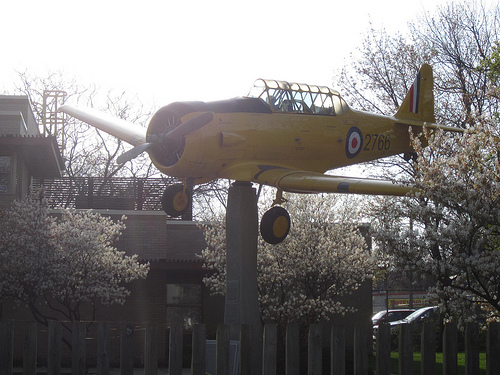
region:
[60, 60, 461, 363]
yellow plane on top of pillar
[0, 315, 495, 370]
wooden fence with grey pickets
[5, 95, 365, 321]
house with different levels and angles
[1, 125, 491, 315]
blossoms on round trees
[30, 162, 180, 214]
railing on elevated floor of house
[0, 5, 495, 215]
bright light over trees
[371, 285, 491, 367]
cars and truck parked by green lawn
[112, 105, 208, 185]
silver propeller in front of circular opening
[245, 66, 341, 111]
curved metal frame over cockpit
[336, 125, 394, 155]
circle with rings next to numbers on side of plane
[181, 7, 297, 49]
White clear cloudless sky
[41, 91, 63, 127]
Big steady metal frame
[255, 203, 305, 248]
Black and yellow wheel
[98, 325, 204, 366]
Grey colored picket fence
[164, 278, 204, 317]
A large clear window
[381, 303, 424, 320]
Two parked motionless cars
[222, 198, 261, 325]
A large stone wall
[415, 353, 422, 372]
Green colored lushy grass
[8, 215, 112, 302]
Small leafy green tree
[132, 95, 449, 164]
A small yellow helicopter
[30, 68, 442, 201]
plane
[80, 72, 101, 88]
white clouds in blue sky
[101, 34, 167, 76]
white clouds in blue sky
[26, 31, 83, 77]
white clouds in blue sky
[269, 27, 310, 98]
white clouds in blue sky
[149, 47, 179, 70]
white clouds in blue sky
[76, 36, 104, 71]
white clouds in blue sky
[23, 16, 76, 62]
white clouds in blue sky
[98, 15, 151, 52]
white clouds in blue sky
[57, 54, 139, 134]
white clouds in blue sky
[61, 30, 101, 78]
white clouds in blue sky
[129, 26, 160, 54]
white clouds in blue sky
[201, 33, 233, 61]
white clouds in blue sky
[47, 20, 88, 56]
white clouds in blue sky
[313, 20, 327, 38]
white clouds in blue sky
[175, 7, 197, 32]
white clouds in blue sky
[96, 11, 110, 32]
white clouds in blue sky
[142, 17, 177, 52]
white clouds in blue sky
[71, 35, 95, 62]
white clouds in blue sky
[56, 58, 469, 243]
yellow plane with one propeller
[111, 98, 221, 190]
nose propeller of small plane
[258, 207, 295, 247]
airplane wheel with yellow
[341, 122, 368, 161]
blue, white and red bullseye on yellow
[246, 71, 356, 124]
cockpit of yellow airplane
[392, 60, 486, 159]
tale of yellow airplane with red white and blue stripe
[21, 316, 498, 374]
top of wooden picket fence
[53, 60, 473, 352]
old fashioned yellow airplane up on post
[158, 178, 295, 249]
landing gear of small yellow airplane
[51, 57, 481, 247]
yellow airplane with red white and blue designs